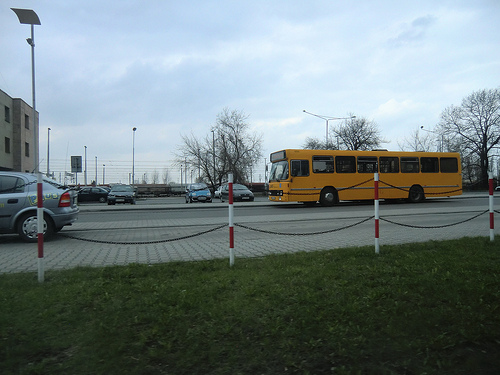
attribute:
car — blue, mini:
[175, 170, 222, 211]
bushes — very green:
[0, 233, 499, 373]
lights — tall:
[123, 117, 142, 175]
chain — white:
[31, 176, 496, 193]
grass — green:
[0, 222, 499, 372]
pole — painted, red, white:
[226, 172, 236, 269]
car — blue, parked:
[186, 176, 214, 204]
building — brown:
[1, 88, 56, 180]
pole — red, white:
[227, 177, 238, 262]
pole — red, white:
[33, 183, 45, 281]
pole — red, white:
[369, 171, 386, 258]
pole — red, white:
[482, 175, 496, 254]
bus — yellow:
[249, 135, 474, 212]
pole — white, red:
[488, 169, 498, 246]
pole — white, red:
[371, 169, 381, 252]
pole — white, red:
[225, 169, 237, 268]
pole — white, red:
[34, 170, 47, 280]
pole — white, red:
[33, 181, 53, 283]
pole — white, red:
[215, 171, 242, 265]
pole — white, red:
[370, 176, 387, 256]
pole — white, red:
[487, 167, 499, 230]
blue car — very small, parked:
[186, 179, 214, 204]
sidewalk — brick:
[183, 240, 234, 256]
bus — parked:
[260, 145, 471, 219]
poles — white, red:
[225, 173, 380, 265]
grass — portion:
[402, 252, 499, 342]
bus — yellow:
[208, 123, 472, 253]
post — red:
[224, 170, 236, 268]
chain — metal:
[43, 206, 497, 244]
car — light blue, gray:
[0, 170, 80, 239]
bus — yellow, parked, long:
[269, 147, 460, 207]